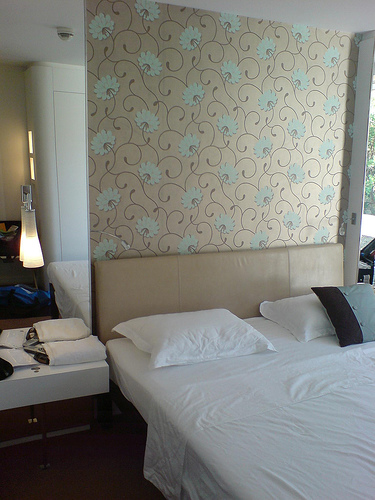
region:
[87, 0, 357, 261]
floral wallpaper on the wall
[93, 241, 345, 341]
a beige headboard of a bed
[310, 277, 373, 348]
a blue and black accent pillow on the bed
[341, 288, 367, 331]
three buttons on the accent pillow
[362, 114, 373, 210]
a window next to the bed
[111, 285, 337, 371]
two white pillows on the bed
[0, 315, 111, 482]
a night stand next to the bed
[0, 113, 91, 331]
a mirror on the wall next to the bed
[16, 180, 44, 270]
lights being reflected in the mirror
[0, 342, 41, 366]
reading material on the nightstand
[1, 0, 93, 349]
A large mirror on the wall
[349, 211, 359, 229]
a switch on the wall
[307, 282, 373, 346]
A black and blue pillow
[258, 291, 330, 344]
A white pillow on a bed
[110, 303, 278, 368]
A white pillow on a bed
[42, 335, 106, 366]
A white towel on a counter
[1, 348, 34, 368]
some paper on a counter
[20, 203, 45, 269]
a pair of lights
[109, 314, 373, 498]
A large bed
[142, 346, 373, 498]
some white sheets on a bed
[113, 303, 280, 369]
a white pillow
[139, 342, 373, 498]
part of a white sheet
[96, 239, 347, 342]
a brown headboard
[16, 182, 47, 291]
a tall desk lamp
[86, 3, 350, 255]
a large wall decoration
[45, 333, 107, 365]
a white towel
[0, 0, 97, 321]
a long wall mirror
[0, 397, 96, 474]
brown drawer cabinets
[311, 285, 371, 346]
part of a decorative pillow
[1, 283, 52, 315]
a blue and black duffel bag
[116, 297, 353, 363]
white pillows on bed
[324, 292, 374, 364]
blue and grey pillow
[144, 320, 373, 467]
white sheets on bed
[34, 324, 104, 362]
white towels on table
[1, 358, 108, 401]
white table near bed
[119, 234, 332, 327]
dark grey head of bed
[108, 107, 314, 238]
grey and blue wall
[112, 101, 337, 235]
blue flowers on wall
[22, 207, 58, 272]
white light on wall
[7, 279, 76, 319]
blue bag under light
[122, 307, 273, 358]
Crispy white pollow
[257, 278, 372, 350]
White pillow with another pillow on it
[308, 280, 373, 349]
Black and blue pillow with buttons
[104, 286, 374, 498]
Bed with white bed sheets and white pillows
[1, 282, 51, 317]
reflection of blue and black bag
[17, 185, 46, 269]
Original and reflection of mirror lamp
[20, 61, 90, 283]
Reflection of white cabinet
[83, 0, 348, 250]
Brown and blue floral wallpaper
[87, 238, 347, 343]
Brown head board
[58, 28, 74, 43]
reflection of smoke dectector